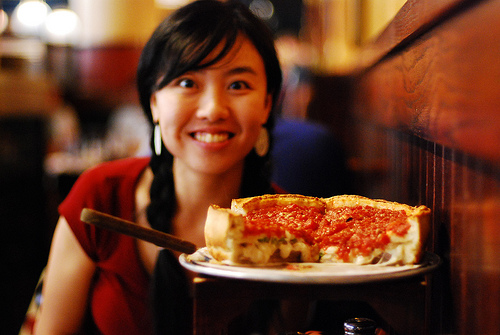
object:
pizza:
[204, 195, 431, 268]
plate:
[179, 246, 433, 283]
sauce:
[243, 204, 410, 247]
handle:
[79, 207, 196, 255]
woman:
[32, 1, 317, 335]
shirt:
[57, 150, 309, 333]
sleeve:
[58, 161, 114, 262]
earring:
[154, 125, 162, 155]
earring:
[255, 129, 269, 157]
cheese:
[241, 239, 403, 263]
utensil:
[80, 207, 291, 267]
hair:
[131, 0, 285, 335]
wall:
[331, 0, 498, 335]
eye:
[174, 77, 200, 89]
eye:
[227, 80, 253, 92]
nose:
[196, 84, 230, 123]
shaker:
[341, 317, 377, 334]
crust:
[204, 205, 243, 266]